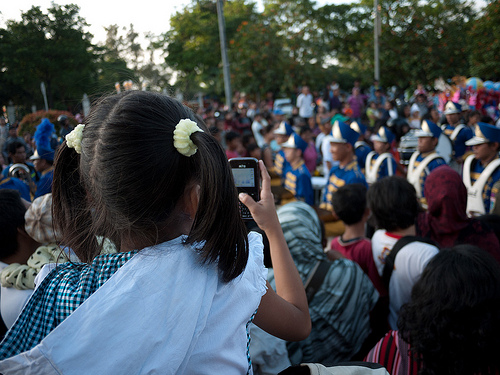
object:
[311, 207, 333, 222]
drum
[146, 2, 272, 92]
trees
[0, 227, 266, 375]
fabric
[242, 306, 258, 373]
end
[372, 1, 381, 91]
pole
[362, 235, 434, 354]
bag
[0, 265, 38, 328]
shirt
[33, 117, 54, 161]
feather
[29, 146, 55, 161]
hat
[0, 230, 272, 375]
shirt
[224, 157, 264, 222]
phone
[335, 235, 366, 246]
collar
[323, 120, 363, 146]
hat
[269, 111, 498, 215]
band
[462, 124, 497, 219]
uniform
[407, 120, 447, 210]
uniform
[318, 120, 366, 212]
uniform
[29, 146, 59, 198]
uniform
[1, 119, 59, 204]
band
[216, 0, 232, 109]
pole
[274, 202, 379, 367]
scarf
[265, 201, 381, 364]
woman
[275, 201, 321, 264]
head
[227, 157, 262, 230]
cell phone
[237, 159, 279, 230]
girl's hand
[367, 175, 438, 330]
people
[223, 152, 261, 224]
phone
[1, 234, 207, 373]
hood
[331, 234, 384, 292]
shirt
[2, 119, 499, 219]
parade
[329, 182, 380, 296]
person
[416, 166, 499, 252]
person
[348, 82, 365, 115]
person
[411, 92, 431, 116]
person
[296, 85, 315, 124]
person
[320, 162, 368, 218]
blue shirt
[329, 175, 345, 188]
gold lines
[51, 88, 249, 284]
hair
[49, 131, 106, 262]
pigtail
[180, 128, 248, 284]
pig tails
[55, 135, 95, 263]
pig tails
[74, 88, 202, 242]
girls head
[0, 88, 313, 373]
girl